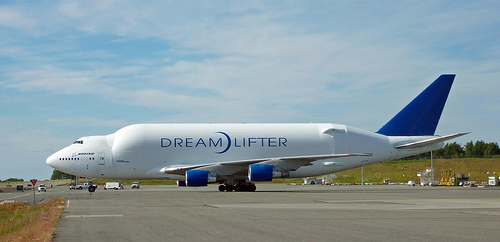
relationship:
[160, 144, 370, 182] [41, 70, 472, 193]
wing of airplane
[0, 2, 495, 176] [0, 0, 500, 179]
clouds in blue sky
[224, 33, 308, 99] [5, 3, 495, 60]
white clouds in blue sky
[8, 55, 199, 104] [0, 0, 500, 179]
cloud in blue sky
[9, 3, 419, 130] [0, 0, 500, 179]
cloud in blue sky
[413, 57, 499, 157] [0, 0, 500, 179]
cloud in blue sky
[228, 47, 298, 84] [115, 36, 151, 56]
clouds in sky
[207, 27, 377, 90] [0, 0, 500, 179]
white clouds in blue sky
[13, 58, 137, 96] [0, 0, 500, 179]
cloud in blue sky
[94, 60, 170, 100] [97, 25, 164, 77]
clouds in sky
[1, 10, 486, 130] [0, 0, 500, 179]
clouds in blue sky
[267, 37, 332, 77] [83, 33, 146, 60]
white clouds in blue sky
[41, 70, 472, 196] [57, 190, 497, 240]
airplane on runway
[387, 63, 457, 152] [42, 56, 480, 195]
tail on airplane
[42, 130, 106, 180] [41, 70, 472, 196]
nose on airplane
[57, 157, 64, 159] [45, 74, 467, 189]
window on airplane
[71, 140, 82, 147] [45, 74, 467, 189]
window on airplane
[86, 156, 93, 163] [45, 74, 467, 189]
window on airplane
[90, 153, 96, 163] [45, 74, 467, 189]
window on airplane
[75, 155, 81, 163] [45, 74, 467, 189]
window on airplane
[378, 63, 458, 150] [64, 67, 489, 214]
tail on plane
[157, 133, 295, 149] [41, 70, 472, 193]
name on airplane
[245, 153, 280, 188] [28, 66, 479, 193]
engines on plane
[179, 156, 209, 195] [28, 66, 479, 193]
engines on plane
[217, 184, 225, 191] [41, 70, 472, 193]
wheel on airplane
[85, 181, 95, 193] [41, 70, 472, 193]
wheel on airplane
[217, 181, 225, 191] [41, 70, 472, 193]
wheel on airplane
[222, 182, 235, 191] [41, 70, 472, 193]
wheel on airplane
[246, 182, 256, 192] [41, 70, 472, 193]
wheel on airplane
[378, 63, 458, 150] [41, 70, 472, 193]
tail on airplane